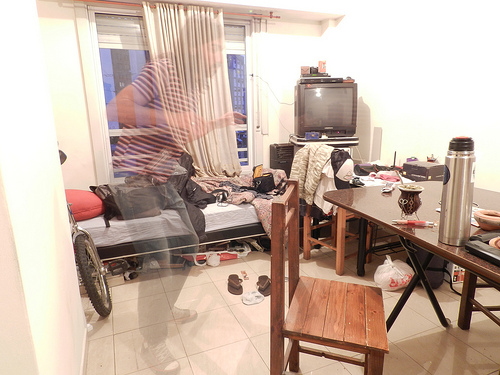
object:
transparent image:
[102, 14, 246, 375]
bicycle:
[67, 201, 115, 326]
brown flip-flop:
[226, 274, 245, 299]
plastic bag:
[371, 254, 416, 295]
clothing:
[288, 143, 343, 207]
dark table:
[322, 178, 498, 339]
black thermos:
[435, 131, 477, 246]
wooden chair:
[265, 177, 390, 373]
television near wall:
[287, 80, 360, 141]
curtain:
[141, 4, 242, 181]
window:
[95, 9, 256, 180]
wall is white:
[322, 0, 500, 193]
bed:
[68, 168, 299, 277]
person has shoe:
[142, 334, 180, 373]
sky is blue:
[95, 44, 250, 175]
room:
[20, 59, 498, 374]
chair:
[264, 181, 390, 373]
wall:
[0, 0, 86, 375]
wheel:
[73, 233, 114, 317]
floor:
[72, 238, 499, 374]